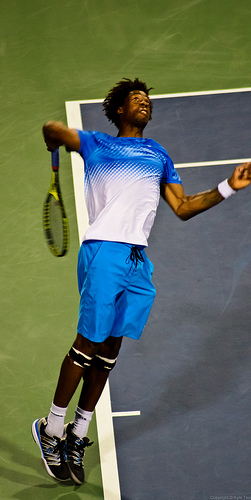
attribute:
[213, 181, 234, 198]
sweatband — white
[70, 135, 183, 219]
shirt — blue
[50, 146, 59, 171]
handle — blue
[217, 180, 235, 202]
wrist band — white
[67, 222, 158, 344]
shorts — blue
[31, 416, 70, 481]
shoe — black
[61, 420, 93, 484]
shoe — black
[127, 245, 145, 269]
cord — black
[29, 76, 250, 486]
he — looking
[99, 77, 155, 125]
hair — black, curly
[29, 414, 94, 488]
tennis shoes — blue, black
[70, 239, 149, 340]
shorts — blue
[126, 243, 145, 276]
string — black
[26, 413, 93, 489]
shoes — silver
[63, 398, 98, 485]
sock — white, medium length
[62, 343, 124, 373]
knee pads — white, black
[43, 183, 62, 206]
racket — yellow 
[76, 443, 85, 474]
lace — black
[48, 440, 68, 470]
lace — black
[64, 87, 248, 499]
play area — gray